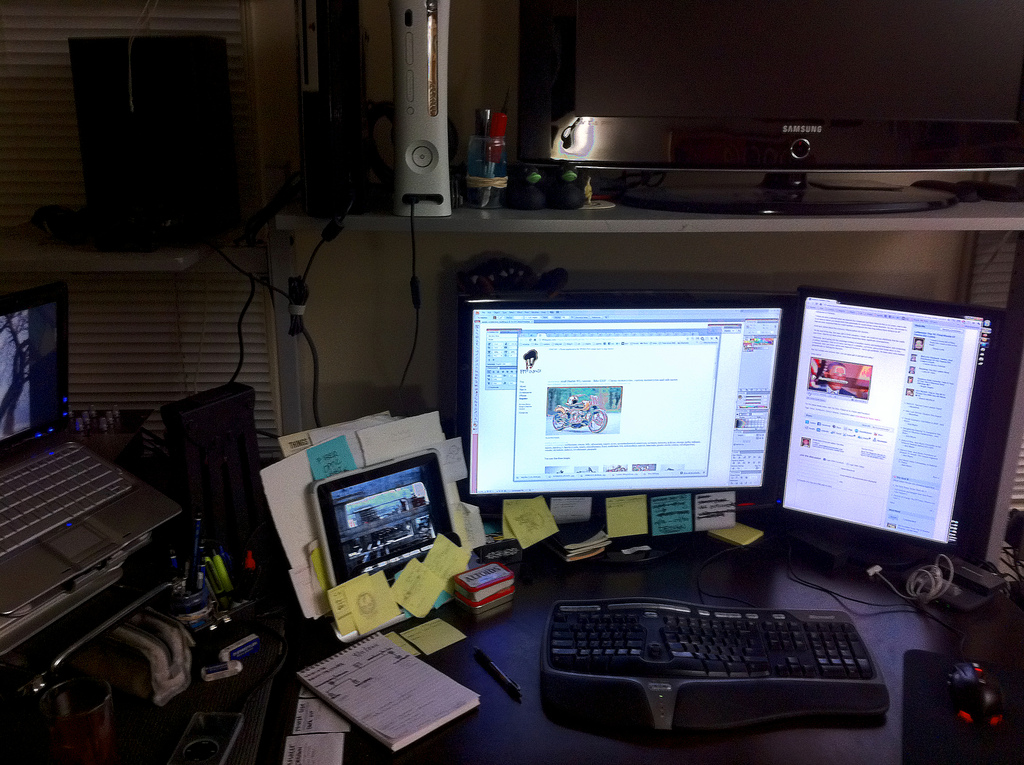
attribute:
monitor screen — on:
[462, 300, 800, 497]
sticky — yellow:
[319, 570, 423, 627]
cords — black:
[173, 223, 362, 390]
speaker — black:
[354, 11, 542, 240]